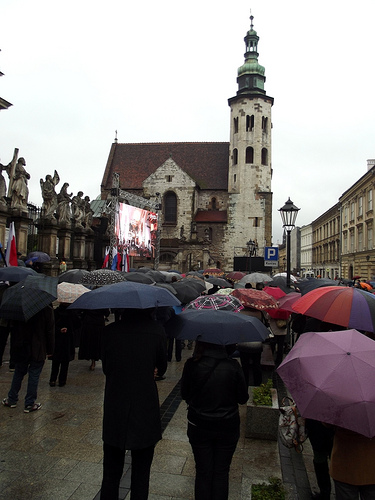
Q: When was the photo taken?
A: During the daytime.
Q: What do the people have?
A: Umbrellas.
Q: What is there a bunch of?
A: Umbrellas.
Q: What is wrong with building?
A: Is old.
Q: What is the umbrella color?
A: Black.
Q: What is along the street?
A: Buildings.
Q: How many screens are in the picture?
A: One.